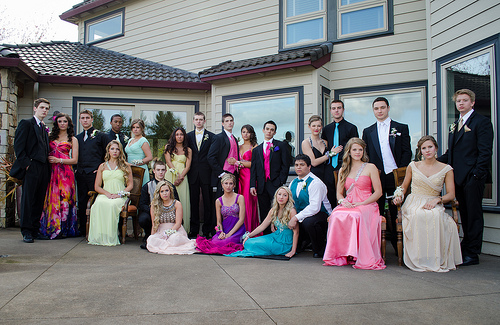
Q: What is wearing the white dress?
A: The girl.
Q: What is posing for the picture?
A: The group of people.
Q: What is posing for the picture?
A: The teens.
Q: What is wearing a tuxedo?
A: The boy.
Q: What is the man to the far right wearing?
A: A black suit.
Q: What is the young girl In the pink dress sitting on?
A: A chair.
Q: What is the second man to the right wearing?
A: A white shirt and a white tie with a black suit coat.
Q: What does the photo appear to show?
A: People in a wedding party.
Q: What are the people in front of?
A: A house.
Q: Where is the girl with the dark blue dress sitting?
A: On the ground.